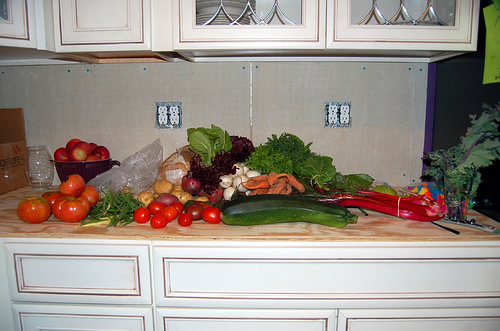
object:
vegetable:
[14, 103, 500, 225]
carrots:
[237, 172, 305, 197]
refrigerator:
[422, 102, 499, 221]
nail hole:
[363, 67, 366, 70]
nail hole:
[408, 68, 411, 71]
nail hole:
[420, 69, 423, 71]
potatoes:
[195, 196, 209, 202]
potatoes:
[171, 190, 194, 205]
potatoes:
[154, 180, 173, 195]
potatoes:
[138, 190, 154, 208]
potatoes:
[174, 185, 183, 191]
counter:
[2, 185, 499, 242]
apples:
[54, 138, 110, 162]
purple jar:
[54, 158, 121, 184]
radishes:
[314, 185, 448, 222]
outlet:
[325, 102, 350, 128]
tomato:
[17, 195, 52, 224]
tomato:
[59, 174, 86, 198]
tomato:
[52, 195, 87, 223]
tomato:
[80, 185, 98, 205]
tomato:
[41, 190, 63, 207]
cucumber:
[220, 194, 357, 227]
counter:
[0, 238, 500, 331]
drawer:
[6, 241, 151, 304]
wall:
[5, 2, 498, 329]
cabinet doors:
[178, 0, 481, 53]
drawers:
[158, 246, 499, 305]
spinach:
[187, 124, 233, 167]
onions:
[157, 176, 223, 206]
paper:
[379, 161, 418, 185]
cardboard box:
[0, 107, 30, 195]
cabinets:
[0, 0, 481, 66]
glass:
[23, 144, 55, 190]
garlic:
[219, 163, 261, 201]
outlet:
[157, 101, 183, 128]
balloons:
[408, 181, 443, 200]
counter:
[0, 52, 486, 200]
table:
[1, 172, 500, 331]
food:
[16, 103, 499, 236]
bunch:
[327, 190, 445, 222]